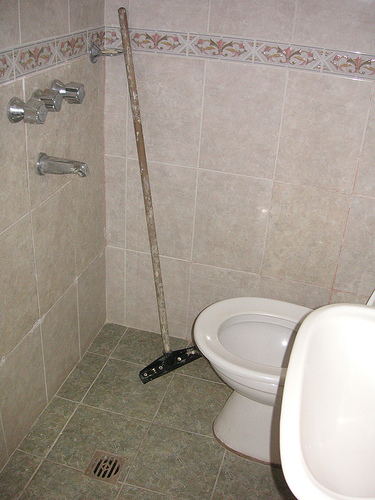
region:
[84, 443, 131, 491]
Shower drain at the bottom of the shower.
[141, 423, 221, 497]
Green tile on the bottom of the bathroom.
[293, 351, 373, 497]
Empty sink in the bathroom.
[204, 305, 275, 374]
Clean toilet seat in the bathroom.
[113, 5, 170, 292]
Handle of paint scraper in the bathroom.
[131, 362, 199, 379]
Bottom piece of paint scraper in the bathroom.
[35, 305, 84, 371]
Tan tile lining the shower.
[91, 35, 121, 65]
Hand towel rack in the bathroom/shower.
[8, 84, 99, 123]
Shower temperature knobs on the wall.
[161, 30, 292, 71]
Pink and green shower lining in the bathroom.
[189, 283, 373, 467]
white toilet with seat up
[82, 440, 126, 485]
silver drain in bathroom floor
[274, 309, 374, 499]
white sink in the bathroom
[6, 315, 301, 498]
green tiles on the bathroom floor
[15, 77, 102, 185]
silver faucet and knobs on wall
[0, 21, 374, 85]
patterned banner on wall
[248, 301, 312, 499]
shadow of the white sink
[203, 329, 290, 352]
glare of light on toilet bowl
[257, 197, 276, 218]
glare of light on wall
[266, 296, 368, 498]
lip of white sink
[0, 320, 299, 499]
Green tile on the floor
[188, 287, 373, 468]
A bright white toilet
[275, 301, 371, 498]
A bright white sink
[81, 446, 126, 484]
A gold drain in the floor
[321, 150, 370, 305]
Red stain in tile grout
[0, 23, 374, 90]
Brown and pink patterned tile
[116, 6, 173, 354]
A wooden handle with paint on it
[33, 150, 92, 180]
A silver faucet in the wall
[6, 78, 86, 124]
Silver knobs in the wall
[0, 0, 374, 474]
Beige tile on the wall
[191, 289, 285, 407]
one white elongated toilet seat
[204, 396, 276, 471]
base of white toilet on floor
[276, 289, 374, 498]
broad white bathroom sink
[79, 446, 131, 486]
tan colored floor bathroom drain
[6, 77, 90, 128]
set of shiny bathroom faucet handles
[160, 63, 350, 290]
large beige bathroom tiles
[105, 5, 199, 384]
large wooden handle squeegee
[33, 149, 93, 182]
one metal bathroom faucet spigot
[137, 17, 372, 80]
colored detail on bathroom tile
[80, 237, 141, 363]
corner tiles in bathroom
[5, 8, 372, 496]
shower sink and toilet combo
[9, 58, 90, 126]
controls for the shower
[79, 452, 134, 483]
drain opening in the floor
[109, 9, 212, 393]
squeegee with wooden handle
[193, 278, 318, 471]
clean white porcelain toilet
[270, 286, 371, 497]
clean white porcelain toilet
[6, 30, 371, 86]
decorative pattern on the tiles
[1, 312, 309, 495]
greenish tile floor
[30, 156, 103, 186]
water faucet in the wall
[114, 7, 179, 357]
wooden handle is stained